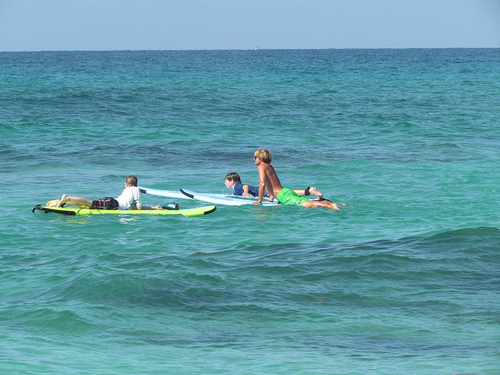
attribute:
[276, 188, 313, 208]
trunks — neon green, shorts, green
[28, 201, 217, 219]
surf board — yellow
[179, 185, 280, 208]
surfboard — black, white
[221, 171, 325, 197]
boy — blond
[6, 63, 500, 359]
water — green, choppy, clear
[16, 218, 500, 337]
wave — shallow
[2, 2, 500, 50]
sky — blue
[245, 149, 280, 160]
hair — blond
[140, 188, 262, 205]
surf board — blue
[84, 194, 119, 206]
shorts — black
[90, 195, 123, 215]
trunks — black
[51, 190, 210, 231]
surfboard — green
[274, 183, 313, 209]
shorts — green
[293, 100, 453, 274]
ocean — bright blue